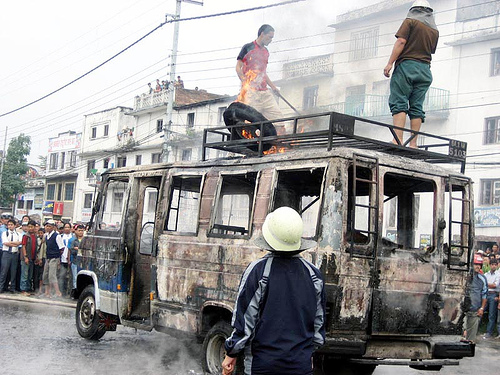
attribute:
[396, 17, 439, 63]
shirt — red 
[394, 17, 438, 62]
t-shirt — brown 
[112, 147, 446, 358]
truck — windowless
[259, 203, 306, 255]
helmet — white 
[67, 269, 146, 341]
tire — in front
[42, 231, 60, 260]
vest — black 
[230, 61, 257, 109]
flame — on top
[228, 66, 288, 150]
fire — orange 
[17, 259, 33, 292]
jeans — blue 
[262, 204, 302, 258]
helmet — white 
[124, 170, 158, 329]
door — open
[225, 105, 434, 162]
railing — black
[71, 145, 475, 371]
van — Burnt 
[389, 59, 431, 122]
pants — blue , green 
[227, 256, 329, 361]
jacket — white 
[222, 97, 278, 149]
tire — burning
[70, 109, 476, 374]
truck — burnt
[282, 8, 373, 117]
smoke — gray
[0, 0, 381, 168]
sky — bright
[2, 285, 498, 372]
street — black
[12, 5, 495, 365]
smoke — light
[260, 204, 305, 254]
hat — hard